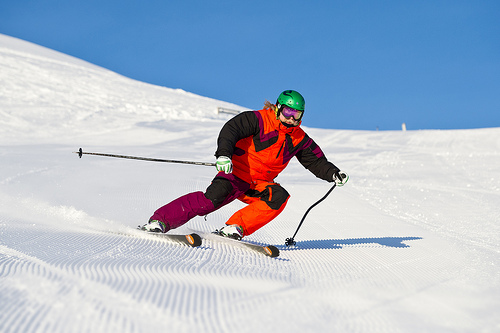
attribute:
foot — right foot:
[140, 217, 167, 232]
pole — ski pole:
[50, 122, 229, 185]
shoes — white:
[137, 212, 248, 242]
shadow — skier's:
[238, 230, 425, 267]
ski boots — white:
[136, 217, 250, 244]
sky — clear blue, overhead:
[2, 2, 499, 137]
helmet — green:
[277, 87, 304, 108]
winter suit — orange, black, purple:
[135, 103, 340, 248]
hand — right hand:
[213, 151, 240, 188]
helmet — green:
[272, 86, 308, 118]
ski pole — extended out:
[74, 147, 220, 169]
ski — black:
[216, 223, 296, 269]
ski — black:
[120, 214, 211, 251]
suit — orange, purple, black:
[133, 103, 369, 258]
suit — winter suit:
[212, 125, 297, 229]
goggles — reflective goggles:
[274, 103, 306, 127]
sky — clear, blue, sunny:
[140, 10, 498, 84]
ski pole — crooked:
[297, 187, 325, 234]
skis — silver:
[114, 205, 291, 267]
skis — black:
[119, 207, 273, 257]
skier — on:
[140, 82, 349, 234]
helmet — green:
[276, 84, 303, 126]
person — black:
[140, 76, 349, 256]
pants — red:
[148, 167, 292, 238]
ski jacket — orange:
[216, 110, 343, 186]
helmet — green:
[273, 85, 300, 105]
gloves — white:
[312, 169, 349, 184]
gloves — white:
[213, 149, 238, 177]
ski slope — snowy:
[20, 45, 489, 317]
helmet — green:
[260, 83, 308, 118]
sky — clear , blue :
[195, 19, 476, 84]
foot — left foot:
[210, 214, 243, 249]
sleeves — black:
[217, 111, 343, 184]